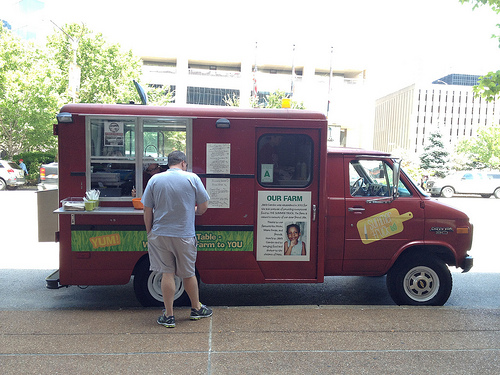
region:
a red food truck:
[26, 59, 497, 334]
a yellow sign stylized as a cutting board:
[351, 201, 417, 256]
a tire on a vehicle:
[388, 250, 451, 325]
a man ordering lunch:
[145, 139, 235, 328]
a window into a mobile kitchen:
[61, 90, 166, 217]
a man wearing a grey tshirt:
[148, 142, 223, 318]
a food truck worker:
[136, 150, 159, 180]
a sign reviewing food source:
[251, 185, 334, 290]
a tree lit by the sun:
[19, 38, 68, 136]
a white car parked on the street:
[423, 157, 494, 197]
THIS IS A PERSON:
[149, 148, 211, 328]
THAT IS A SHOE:
[151, 303, 185, 330]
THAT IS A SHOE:
[194, 291, 210, 324]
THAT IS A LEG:
[158, 260, 180, 327]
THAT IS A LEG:
[189, 270, 221, 319]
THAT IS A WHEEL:
[396, 255, 456, 305]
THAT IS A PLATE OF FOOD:
[74, 183, 99, 216]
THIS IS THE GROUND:
[80, 305, 117, 337]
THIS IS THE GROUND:
[263, 340, 342, 367]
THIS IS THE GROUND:
[329, 332, 392, 359]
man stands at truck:
[122, 141, 217, 290]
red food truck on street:
[54, 100, 469, 307]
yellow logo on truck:
[340, 198, 429, 245]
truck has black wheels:
[390, 250, 446, 317]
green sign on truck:
[54, 226, 268, 267]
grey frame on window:
[77, 116, 207, 223]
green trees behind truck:
[2, 6, 144, 148]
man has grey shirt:
[138, 159, 218, 262]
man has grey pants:
[142, 232, 214, 258]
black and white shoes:
[152, 287, 221, 337]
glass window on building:
[416, 89, 423, 101]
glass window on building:
[423, 88, 428, 101]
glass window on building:
[430, 87, 435, 103]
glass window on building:
[445, 88, 450, 108]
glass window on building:
[462, 89, 468, 104]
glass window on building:
[415, 114, 420, 122]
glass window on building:
[422, 115, 427, 125]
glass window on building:
[429, 114, 434, 124]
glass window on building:
[455, 116, 461, 126]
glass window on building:
[454, 126, 461, 138]